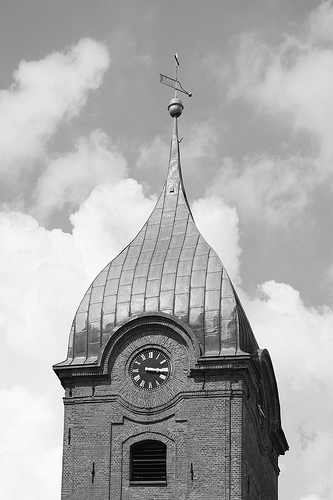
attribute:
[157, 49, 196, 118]
weathervane — old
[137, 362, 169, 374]
time — 3:15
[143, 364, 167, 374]
arms — white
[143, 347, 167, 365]
numbers — roman numerals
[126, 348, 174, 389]
clock — round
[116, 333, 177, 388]
clock — numbered, white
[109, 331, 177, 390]
clock — white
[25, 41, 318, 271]
sky — cloudy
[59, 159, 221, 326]
tower — tiled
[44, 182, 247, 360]
tiles — reflecting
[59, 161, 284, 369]
tiles — shiny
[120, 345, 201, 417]
clock — pointing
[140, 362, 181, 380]
hand — hour, pointing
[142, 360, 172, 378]
hand — minute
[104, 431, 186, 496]
window — black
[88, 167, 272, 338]
roofing — metal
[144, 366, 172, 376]
markings — hour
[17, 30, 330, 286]
sky — cloudy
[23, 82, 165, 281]
clouds — fluffy, white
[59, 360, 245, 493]
building — brick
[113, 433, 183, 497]
windows — shuttered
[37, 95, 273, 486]
building — intricate, designed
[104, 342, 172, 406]
clock — roman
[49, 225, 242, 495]
building — brick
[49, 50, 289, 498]
tower — old, clock, brick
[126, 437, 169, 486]
window — grated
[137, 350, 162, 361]
numerals — roman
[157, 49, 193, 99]
vane — weather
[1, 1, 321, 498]
sky — cloudy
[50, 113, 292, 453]
roof — metallic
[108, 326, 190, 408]
bricks — circularly, lined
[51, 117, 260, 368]
roof — shiny tile, pointed, tiled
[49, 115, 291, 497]
tower — brick, clock